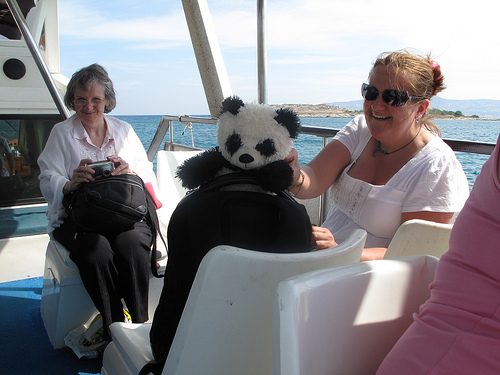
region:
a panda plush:
[170, 93, 303, 201]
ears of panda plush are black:
[207, 90, 304, 138]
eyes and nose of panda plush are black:
[221, 130, 276, 166]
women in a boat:
[0, 0, 499, 371]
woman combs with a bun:
[283, 45, 468, 257]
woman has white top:
[281, 41, 473, 271]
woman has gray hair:
[41, 60, 156, 205]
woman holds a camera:
[26, 64, 161, 201]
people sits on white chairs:
[111, 60, 499, 373]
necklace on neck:
[361, 131, 428, 162]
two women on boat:
[53, 30, 448, 230]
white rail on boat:
[162, 17, 269, 91]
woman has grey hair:
[66, 65, 110, 108]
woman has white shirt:
[23, 110, 143, 195]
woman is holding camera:
[80, 157, 120, 193]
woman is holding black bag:
[72, 169, 143, 225]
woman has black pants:
[75, 227, 187, 351]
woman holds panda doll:
[197, 101, 346, 220]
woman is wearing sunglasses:
[359, 74, 408, 115]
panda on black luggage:
[176, 173, 333, 310]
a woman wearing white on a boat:
[313, 48, 456, 250]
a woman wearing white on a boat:
[41, 55, 151, 162]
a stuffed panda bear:
[176, 91, 305, 194]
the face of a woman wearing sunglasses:
[357, 70, 412, 136]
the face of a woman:
[68, 80, 113, 125]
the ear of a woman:
[416, 96, 429, 120]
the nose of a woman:
[84, 97, 96, 114]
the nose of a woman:
[368, 94, 390, 115]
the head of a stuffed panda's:
[209, 92, 301, 169]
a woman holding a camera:
[31, 55, 151, 190]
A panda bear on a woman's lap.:
[168, 85, 327, 215]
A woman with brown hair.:
[352, 43, 464, 105]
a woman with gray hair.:
[50, 58, 141, 128]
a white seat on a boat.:
[273, 248, 447, 373]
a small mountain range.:
[322, 90, 497, 116]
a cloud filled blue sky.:
[58, 5, 498, 122]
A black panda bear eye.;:
[250, 130, 285, 162]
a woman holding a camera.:
[38, 148, 160, 335]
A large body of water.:
[110, 108, 497, 193]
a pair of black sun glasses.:
[343, 75, 428, 111]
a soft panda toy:
[179, 98, 296, 193]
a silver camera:
[85, 162, 117, 181]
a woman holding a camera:
[37, 63, 151, 319]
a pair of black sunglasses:
[361, 83, 429, 110]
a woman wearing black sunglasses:
[289, 53, 471, 260]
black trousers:
[72, 220, 152, 317]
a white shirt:
[39, 115, 161, 233]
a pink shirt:
[377, 143, 499, 373]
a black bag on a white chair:
[147, 190, 312, 355]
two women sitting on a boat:
[38, 50, 471, 341]